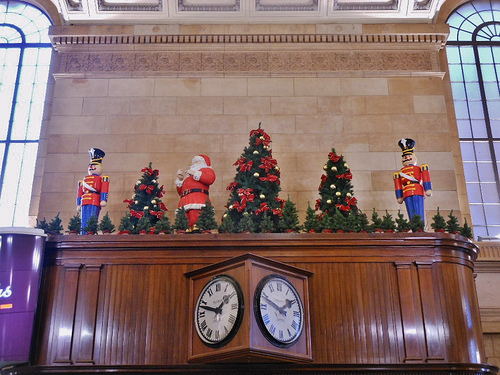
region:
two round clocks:
[180, 252, 317, 359]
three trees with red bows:
[120, 120, 367, 245]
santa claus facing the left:
[167, 148, 224, 233]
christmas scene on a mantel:
[36, 122, 471, 272]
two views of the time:
[178, 252, 328, 367]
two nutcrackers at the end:
[65, 125, 442, 242]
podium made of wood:
[40, 207, 494, 372]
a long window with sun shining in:
[2, 10, 52, 228]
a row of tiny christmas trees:
[38, 207, 479, 244]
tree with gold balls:
[229, 118, 285, 231]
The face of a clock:
[254, 272, 305, 348]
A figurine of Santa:
[176, 151, 215, 226]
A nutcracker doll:
[393, 134, 430, 231]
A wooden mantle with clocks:
[37, 234, 489, 373]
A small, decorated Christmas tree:
[217, 122, 297, 234]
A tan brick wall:
[60, 82, 435, 121]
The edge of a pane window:
[1, 7, 57, 215]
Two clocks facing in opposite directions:
[185, 264, 307, 357]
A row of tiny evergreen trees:
[350, 206, 417, 237]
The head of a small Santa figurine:
[187, 150, 209, 165]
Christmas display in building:
[67, 138, 447, 242]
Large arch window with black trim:
[443, 2, 497, 239]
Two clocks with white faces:
[172, 259, 317, 359]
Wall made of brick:
[69, 61, 440, 164]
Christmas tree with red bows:
[209, 117, 307, 232]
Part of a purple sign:
[0, 203, 51, 374]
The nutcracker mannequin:
[74, 143, 114, 234]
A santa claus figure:
[174, 138, 221, 234]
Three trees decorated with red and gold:
[122, 122, 374, 242]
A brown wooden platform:
[36, 221, 489, 372]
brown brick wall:
[91, 82, 201, 135]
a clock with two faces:
[179, 257, 327, 349]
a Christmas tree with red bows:
[218, 111, 285, 231]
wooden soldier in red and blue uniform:
[378, 127, 454, 244]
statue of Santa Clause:
[163, 145, 235, 234]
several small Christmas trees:
[131, 205, 351, 242]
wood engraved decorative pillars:
[51, 248, 111, 365]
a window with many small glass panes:
[450, 13, 497, 142]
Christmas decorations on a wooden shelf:
[44, 129, 480, 371]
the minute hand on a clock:
[191, 296, 218, 318]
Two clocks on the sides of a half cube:
[171, 260, 348, 362]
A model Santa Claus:
[163, 118, 223, 243]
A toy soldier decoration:
[361, 112, 447, 239]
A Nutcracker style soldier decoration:
[63, 135, 135, 250]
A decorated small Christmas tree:
[219, 100, 292, 247]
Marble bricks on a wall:
[136, 79, 320, 127]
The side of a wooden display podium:
[333, 265, 395, 355]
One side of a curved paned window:
[435, 5, 497, 250]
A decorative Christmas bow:
[231, 182, 256, 209]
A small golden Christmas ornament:
[326, 162, 341, 176]